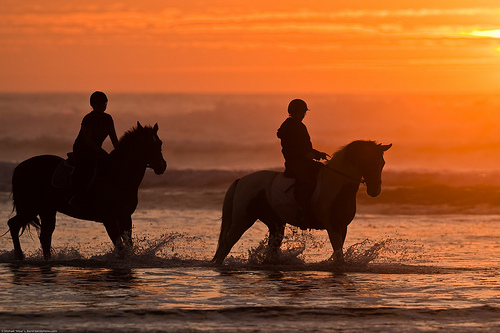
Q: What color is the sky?
A: Orange.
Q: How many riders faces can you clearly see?
A: Zero.